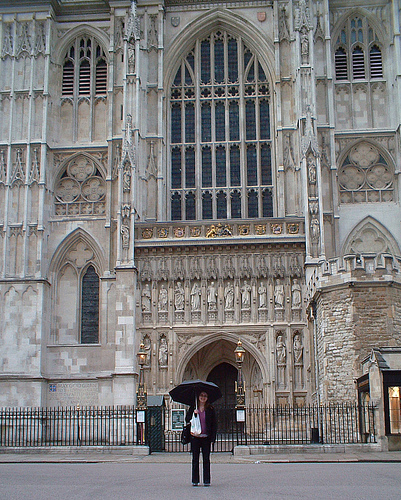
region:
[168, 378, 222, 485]
the woman is standing on a sidewalk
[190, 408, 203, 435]
a white plastic bag in the woman's hand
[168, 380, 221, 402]
the umbrella is black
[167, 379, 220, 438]
a woman is holding an umbrella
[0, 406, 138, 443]
a short black fence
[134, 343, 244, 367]
the lights are on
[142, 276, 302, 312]
a row of statues on the building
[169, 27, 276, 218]
a large detailed window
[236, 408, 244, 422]
a sign on the fence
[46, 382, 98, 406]
an engraving on the wall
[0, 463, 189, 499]
paved road for easier travel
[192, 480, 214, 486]
shoes for both feet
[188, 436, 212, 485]
black pants for wearing on the legs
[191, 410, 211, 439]
purple v-neck shirt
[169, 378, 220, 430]
umbrella used as rain shield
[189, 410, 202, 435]
plastic bag used for holding recently purchased items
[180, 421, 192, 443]
black hand bag used for holding the necessities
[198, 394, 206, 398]
glasses used for vision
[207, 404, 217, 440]
black jacket used for warmth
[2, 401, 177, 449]
fence alongside the perimeter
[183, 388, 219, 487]
Woman standing in front a large building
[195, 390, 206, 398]
Glasses on the woman's face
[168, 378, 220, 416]
Umbrella in the woman's hand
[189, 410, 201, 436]
Plastic bag in the woman's hand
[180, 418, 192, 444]
Purse hanging on the woman's arm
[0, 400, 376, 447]
Metal fence in front of the building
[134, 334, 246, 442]
Lamps in front of the building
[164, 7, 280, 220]
Big window on the building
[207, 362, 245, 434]
Door of the building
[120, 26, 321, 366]
Statues on the building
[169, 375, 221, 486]
A standing young woman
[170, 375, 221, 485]
The posing young woman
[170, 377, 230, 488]
The woman holding an umbrella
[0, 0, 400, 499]
The woman outside a building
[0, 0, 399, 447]
An ancient local building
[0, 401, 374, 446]
The dark colored metallic fence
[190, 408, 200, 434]
A white held paper bag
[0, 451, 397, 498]
A tarmacked road outside the building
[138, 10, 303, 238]
The high large window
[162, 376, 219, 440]
a person holding an umbrella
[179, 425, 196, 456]
a person holding a black bag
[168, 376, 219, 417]
a person under an umbrella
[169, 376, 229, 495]
a person standing in front of a cathedral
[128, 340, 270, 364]
street lights in the entrance of cathedral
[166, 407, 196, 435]
a signage hanging on fence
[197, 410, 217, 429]
a person wearing a purple shirt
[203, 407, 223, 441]
a person wearing a black jacket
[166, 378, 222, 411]
a umbrella shielding a person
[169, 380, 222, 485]
woman standing with black umbrella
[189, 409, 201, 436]
plastic bag being held up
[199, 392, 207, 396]
dark eye glasses being worn by woman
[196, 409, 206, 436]
purple shirt being worn by woman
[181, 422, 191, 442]
black bag being carried by woman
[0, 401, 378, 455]
black wrought iron fence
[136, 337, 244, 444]
green and gold decorative lamp lights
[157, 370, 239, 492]
umbrella being held by woman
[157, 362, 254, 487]
umbrella being held by woman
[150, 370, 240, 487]
umbrella being held by woman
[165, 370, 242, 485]
umbrella being held by woman